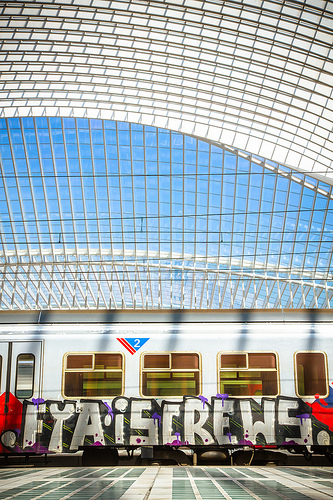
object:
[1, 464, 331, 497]
floor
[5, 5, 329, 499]
train terminal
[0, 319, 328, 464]
train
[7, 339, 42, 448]
door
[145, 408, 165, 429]
graffiti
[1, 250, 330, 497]
train station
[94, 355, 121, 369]
window of  train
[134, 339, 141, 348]
number  the train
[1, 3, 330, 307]
top of terminal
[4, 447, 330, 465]
bottom of train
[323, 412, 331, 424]
graffiti is red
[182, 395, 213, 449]
letter "r"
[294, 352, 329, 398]
back window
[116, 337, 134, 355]
two red stripes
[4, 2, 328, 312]
glass roof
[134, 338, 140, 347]
2 is white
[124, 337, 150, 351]
blue triangle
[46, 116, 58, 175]
white metal beams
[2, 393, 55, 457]
purple paint drips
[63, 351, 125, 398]
three windows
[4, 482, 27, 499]
green stripe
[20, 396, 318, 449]
writing on the train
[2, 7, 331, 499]
giant cage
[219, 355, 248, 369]
window on a train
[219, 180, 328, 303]
part of the sky.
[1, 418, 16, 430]
red spray paint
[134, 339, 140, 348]
number 2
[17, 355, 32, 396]
window on a door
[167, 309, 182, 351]
shadow cast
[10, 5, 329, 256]
metal scaffolding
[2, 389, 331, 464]
graffiti on a train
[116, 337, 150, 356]
this is a triangle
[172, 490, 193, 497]
green tile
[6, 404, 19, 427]
red on the door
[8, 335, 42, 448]
doors are closed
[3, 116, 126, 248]
blue sky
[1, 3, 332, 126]
roof is white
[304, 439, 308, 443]
purple spot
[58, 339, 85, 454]
part of a train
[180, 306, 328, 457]
side of a train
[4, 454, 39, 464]
part of a rail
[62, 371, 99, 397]
part of a window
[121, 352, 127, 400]
edge of a window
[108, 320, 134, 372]
"part of train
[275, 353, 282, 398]
edge of a window